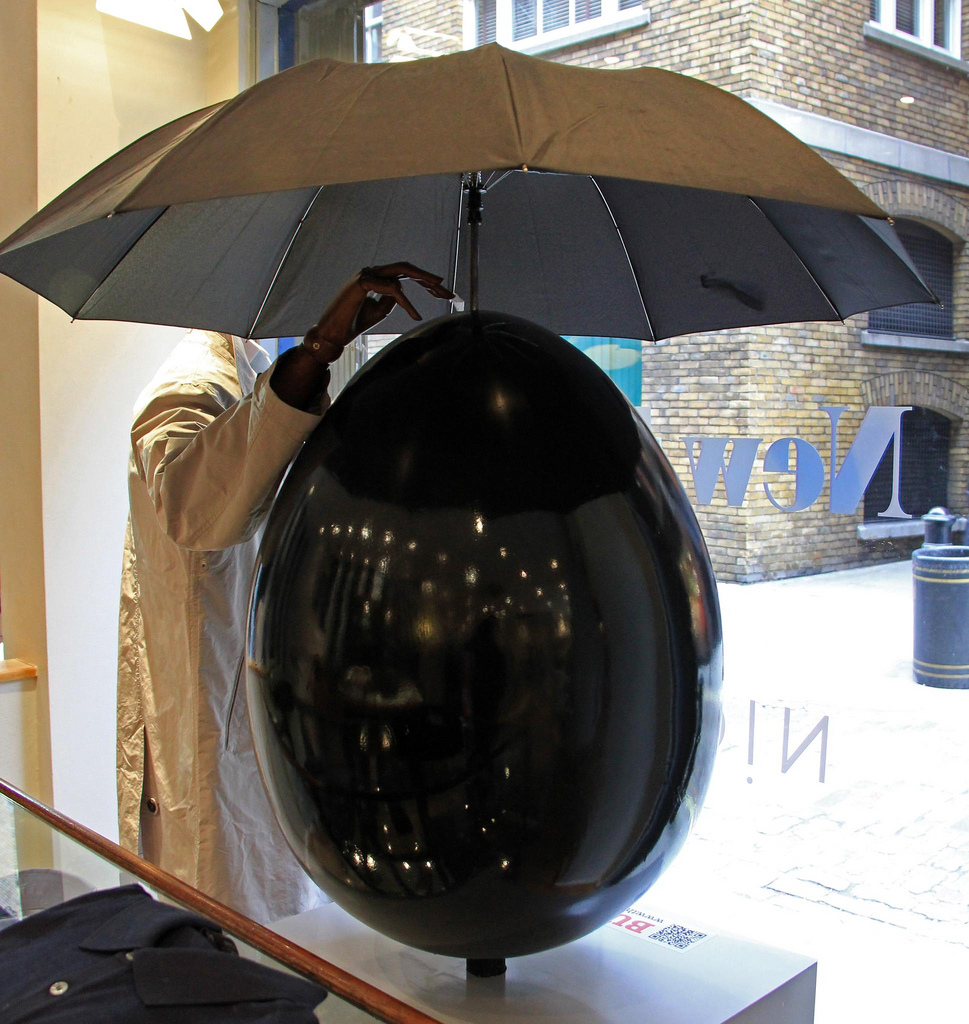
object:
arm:
[130, 262, 453, 550]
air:
[0, 0, 968, 262]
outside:
[368, 0, 969, 1022]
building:
[358, 0, 968, 580]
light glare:
[401, 859, 411, 875]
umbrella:
[0, 43, 944, 342]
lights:
[315, 515, 579, 635]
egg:
[244, 310, 726, 961]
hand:
[303, 262, 458, 364]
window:
[33, 0, 969, 1018]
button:
[46, 970, 74, 997]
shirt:
[0, 882, 328, 1022]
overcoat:
[115, 247, 333, 931]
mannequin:
[116, 262, 459, 925]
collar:
[233, 334, 273, 397]